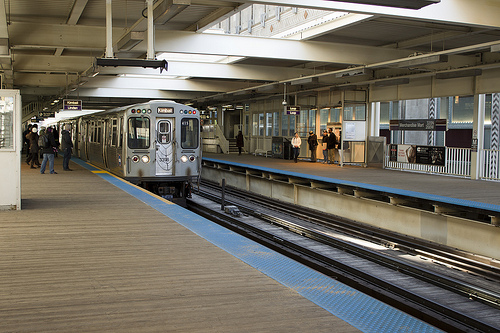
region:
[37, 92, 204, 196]
train in station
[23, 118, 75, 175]
people in station to left of train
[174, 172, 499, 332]
train tracks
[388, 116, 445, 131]
sign in station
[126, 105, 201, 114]
red and green lights on train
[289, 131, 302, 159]
person in white shirt to right of train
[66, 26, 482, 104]
metal rafters above train tracks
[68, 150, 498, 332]
blue safety bumps closest to walking area drop off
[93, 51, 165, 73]
hanging LED sign above train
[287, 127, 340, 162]
people waiting to right of train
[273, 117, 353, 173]
Group of five people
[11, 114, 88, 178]
Large group of people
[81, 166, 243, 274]
Yellow and blue strip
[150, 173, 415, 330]
Grey train tracks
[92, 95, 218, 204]
Grey train with a light grey door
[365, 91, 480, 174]
Dark red sign with white letters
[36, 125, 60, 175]
Man wearing jeans and backpack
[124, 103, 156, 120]
Group of round lights on train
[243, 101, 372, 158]
Line of multiple windows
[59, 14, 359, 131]
Sunlight shining onto ceiling rafters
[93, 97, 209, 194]
grey subway car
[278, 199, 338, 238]
metal subway tracks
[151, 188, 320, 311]
blue painted subway platform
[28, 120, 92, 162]
people on a subway platform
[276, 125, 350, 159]
a group of people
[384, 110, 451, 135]
a hanging banner sign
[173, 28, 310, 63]
white painted steel girder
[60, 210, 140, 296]
grey subway platform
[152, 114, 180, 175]
a door on a subway car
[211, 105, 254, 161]
stairs on a subway platform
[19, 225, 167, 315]
Platform of the station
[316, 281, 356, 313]
Blue border between the platform and the tracks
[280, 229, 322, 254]
Track the train is traveling on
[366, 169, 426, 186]
Platform on the far side of the train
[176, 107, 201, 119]
Set of four lights on the top right of the train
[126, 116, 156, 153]
Left front window of the train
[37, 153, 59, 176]
Jeans of the passenger waiting to board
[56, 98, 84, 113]
Lighted sign hanging from the ceiling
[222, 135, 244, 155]
Stairs on the platform furthest from us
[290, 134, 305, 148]
White shirt on the person on the platform farthest from us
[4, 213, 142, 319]
A wooden floor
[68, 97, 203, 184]
A subway car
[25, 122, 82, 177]
A group of people waiting on the subway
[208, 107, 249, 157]
A woman walking by stairs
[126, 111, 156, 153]
The window of a subway car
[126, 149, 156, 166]
Lights on the front of a subway car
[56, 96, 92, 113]
A sign in a subway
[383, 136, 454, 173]
An advertisement in a subway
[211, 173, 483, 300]
The rails in a subway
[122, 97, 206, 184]
The front of a subway car